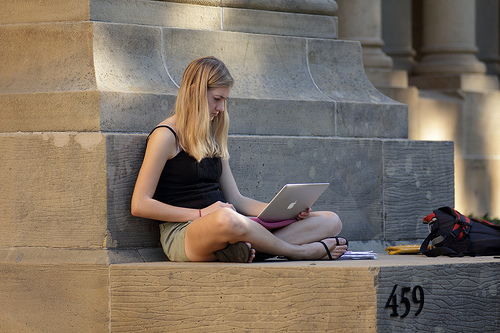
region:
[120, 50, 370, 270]
Woman sits next to building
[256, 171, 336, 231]
Laptop brand is apple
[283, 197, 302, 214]
Apple logotype on laptop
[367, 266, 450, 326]
Number on building is 459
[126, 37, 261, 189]
Woman has long hair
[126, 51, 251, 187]
Woman is blonde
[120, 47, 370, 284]
Woman wears flip flops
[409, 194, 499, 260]
Backpack sits on floor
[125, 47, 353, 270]
Girl sits with legs crossed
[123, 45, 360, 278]
Girl lean on wall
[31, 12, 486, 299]
woman outside studying on computer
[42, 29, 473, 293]
lady outside studying on computer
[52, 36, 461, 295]
person outside studying on computer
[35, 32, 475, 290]
female outside studying on computer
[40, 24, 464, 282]
woman sitting outside with computer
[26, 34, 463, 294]
lady sitting outside with computer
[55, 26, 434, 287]
female sitting outside with computer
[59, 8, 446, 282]
person sitting outside with computer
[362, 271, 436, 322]
number 459 showing on concrete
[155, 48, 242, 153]
lady with long hair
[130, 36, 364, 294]
Woman working on laptop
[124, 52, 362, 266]
Blond woman sitting cross legged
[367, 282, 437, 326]
Street number on curb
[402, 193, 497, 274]
Backpack laying on sidewalk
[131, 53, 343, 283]
Woman wearing black tank top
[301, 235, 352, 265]
Sandal on woman's foot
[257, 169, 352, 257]
Back of laptop monitor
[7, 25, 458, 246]
Stone pedestal of a building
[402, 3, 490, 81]
Stone column in background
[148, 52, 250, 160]
Blond hair on woman's head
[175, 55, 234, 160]
medium length blond hair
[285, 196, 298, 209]
white apple logo on computer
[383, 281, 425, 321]
black numbers 459 on stone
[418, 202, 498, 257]
black and red backpack sitting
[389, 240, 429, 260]
yellow paper envelope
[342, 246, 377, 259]
stack of white papers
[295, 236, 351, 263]
foot of woman in flip flop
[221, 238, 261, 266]
foot of woman in flip flop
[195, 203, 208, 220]
red hair elastic on wrist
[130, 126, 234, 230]
arm of woman sitting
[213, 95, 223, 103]
the eye of a person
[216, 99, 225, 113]
the nose of a person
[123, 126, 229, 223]
the hand of a person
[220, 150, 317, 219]
the hand of a person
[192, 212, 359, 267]
the leg of a person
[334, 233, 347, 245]
the leg finger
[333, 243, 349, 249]
the leg finger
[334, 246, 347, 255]
the leg finger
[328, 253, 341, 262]
the leg finger